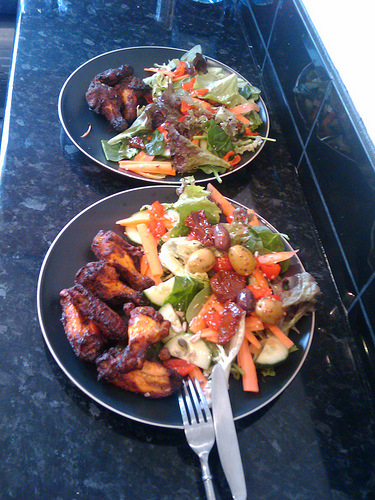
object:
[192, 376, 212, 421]
tine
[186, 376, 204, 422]
tine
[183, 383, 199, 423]
tine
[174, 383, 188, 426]
tine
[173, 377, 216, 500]
silver fork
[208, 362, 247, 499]
knife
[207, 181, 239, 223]
carrot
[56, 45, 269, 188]
plate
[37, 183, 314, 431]
plate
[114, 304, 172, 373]
chicken